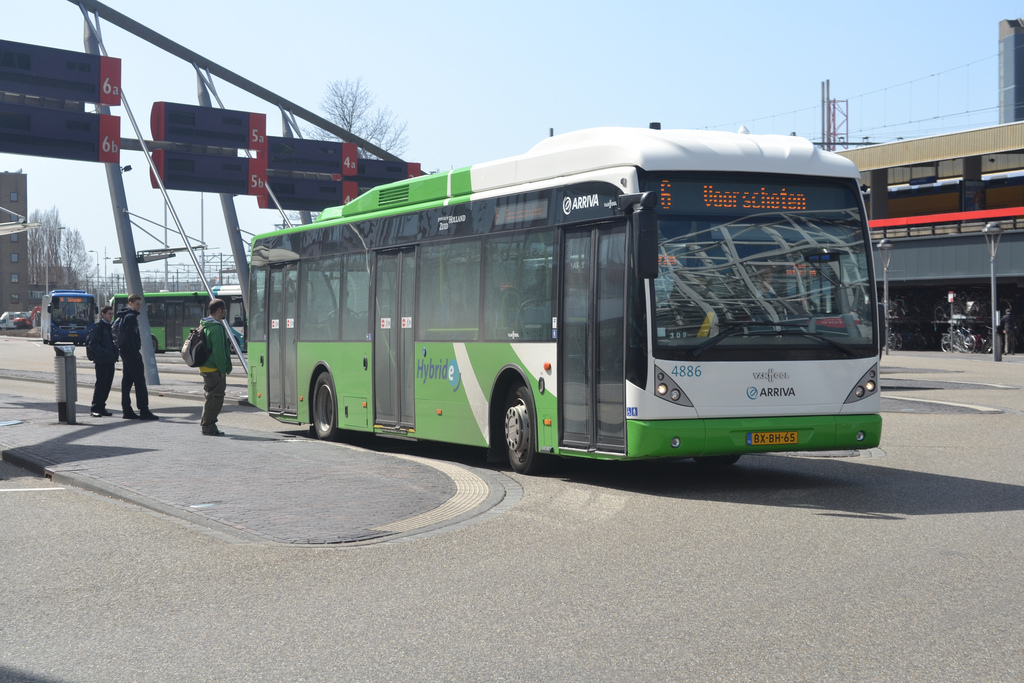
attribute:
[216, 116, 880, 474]
bus — white, green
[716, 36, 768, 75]
sky — blue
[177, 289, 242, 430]
jacket — green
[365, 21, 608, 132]
clouds — white